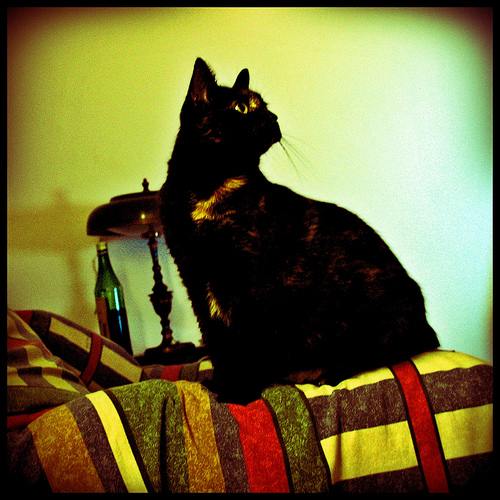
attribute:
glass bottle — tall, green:
[85, 232, 138, 362]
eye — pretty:
[230, 96, 251, 118]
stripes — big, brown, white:
[128, 324, 445, 497]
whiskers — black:
[277, 127, 309, 172]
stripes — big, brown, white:
[5, 329, 474, 488]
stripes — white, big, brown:
[28, 389, 148, 492]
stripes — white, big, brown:
[294, 347, 491, 491]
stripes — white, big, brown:
[51, 313, 143, 382]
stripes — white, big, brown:
[8, 329, 80, 396]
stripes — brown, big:
[225, 394, 289, 492]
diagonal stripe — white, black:
[51, 317, 166, 372]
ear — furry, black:
[230, 67, 250, 91]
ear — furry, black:
[183, 57, 218, 102]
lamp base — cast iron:
[101, 197, 227, 381]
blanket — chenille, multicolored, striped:
[30, 376, 490, 492]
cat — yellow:
[156, 56, 442, 402]